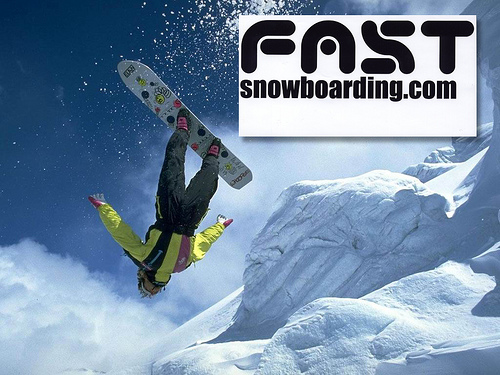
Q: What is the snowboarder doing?
A: A flip.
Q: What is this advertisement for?
A: Fastsnowboarding.com.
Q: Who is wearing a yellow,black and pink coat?
A: The snow boarder.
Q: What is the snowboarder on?
A: A white snowboard.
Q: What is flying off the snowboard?
A: Snow.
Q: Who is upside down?
A: The snowboarder.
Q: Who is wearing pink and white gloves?
A: The snowboarder.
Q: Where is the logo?
A: In the upper right corner.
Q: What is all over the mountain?
A: Snow and ice.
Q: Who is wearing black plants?
A: The snowboarder.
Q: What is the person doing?
A: Jumping in air.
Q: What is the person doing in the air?
A: Snowboarding.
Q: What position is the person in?
A: Upside down.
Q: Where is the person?
A: Snow mountains.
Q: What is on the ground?
A: Snow.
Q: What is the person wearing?
A: Snowsuit.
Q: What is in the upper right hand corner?
A: Black and white sign.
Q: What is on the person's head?
A: Helmet.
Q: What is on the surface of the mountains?
A: Shadows.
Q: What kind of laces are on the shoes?
A: Orange.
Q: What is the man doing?
A: Snowboarding.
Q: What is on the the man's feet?
A: A snowboard.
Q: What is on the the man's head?
A: A ski cap.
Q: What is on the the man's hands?
A: Gloves.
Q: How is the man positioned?
A: Upside down.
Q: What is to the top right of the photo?
A: White fast logo.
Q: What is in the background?
A: Mountains.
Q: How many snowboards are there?
A: One.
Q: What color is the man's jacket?
A: Yellow, pink, black.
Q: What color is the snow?
A: White.